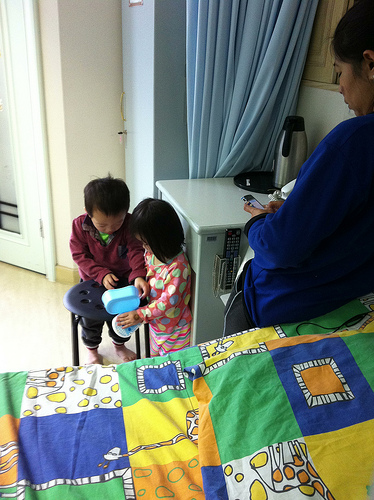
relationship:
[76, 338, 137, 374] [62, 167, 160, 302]
foot of boy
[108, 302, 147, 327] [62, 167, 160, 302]
hand of boy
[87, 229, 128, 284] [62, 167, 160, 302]
arm of boy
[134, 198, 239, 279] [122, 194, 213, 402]
head of girl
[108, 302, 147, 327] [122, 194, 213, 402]
hand of girl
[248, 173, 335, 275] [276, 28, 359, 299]
arm of woman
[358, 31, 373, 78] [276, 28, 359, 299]
ear of woman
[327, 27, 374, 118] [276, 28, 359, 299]
head of woman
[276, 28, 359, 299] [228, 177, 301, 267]
woman has phone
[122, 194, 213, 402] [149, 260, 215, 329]
girl has polka dots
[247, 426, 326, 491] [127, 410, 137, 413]
giraffe on blanket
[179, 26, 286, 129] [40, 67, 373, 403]
curtain in kitchen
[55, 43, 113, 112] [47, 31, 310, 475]
wall in room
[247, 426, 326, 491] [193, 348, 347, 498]
giraffe on bedspread